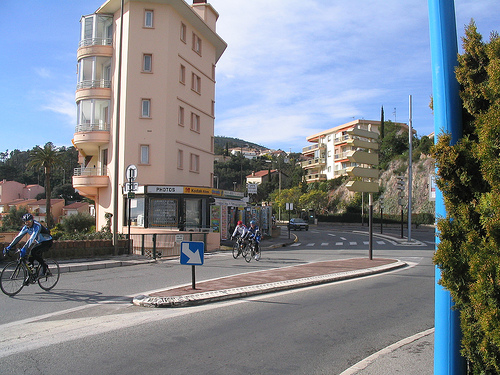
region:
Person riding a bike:
[0, 210, 67, 300]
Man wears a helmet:
[1, 210, 65, 304]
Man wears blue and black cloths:
[6, 207, 69, 304]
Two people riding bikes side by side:
[223, 211, 270, 274]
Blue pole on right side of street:
[424, 1, 469, 372]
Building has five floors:
[67, 1, 236, 243]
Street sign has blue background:
[177, 234, 210, 291]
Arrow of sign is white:
[172, 236, 213, 272]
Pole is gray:
[394, 89, 426, 248]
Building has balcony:
[63, 0, 164, 208]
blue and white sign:
[171, 231, 227, 312]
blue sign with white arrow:
[171, 234, 215, 294]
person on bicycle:
[13, 214, 79, 319]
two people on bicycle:
[220, 211, 279, 270]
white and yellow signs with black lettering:
[145, 174, 245, 216]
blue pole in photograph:
[391, 1, 494, 371]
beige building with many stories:
[73, 5, 219, 245]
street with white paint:
[273, 199, 416, 289]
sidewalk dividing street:
[128, 245, 410, 310]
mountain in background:
[6, 114, 306, 206]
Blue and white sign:
[174, 239, 216, 273]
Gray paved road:
[90, 269, 229, 371]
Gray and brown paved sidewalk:
[236, 235, 407, 310]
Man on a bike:
[3, 213, 72, 294]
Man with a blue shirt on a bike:
[6, 208, 59, 269]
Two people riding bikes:
[230, 216, 267, 262]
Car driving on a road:
[283, 216, 315, 234]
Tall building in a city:
[68, 1, 233, 258]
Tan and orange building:
[293, 113, 401, 233]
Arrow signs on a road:
[344, 126, 391, 218]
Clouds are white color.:
[217, 10, 315, 65]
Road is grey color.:
[166, 310, 286, 370]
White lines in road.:
[295, 225, 417, 267]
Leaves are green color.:
[446, 145, 496, 221]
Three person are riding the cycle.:
[10, 205, 275, 291]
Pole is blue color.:
[420, 15, 475, 350]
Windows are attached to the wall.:
[125, 15, 215, 180]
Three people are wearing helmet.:
[7, 205, 272, 250]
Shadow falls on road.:
[21, 240, 376, 340]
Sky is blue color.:
[8, 16, 68, 132]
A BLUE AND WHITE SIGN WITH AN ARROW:
[177, 237, 206, 267]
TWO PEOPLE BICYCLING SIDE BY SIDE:
[226, 217, 268, 265]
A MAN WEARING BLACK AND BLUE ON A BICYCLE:
[0, 211, 65, 299]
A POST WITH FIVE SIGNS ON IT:
[338, 117, 389, 268]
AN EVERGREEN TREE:
[423, 15, 498, 373]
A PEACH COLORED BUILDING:
[65, 0, 229, 259]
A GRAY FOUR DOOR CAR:
[285, 213, 309, 232]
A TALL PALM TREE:
[22, 139, 74, 235]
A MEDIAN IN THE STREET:
[127, 245, 417, 315]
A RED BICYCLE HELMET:
[235, 216, 244, 230]